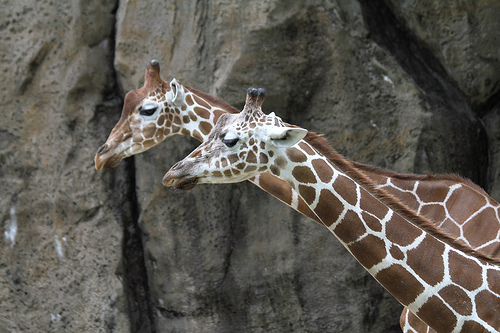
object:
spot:
[385, 213, 422, 247]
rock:
[113, 0, 486, 331]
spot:
[437, 283, 472, 315]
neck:
[270, 136, 500, 333]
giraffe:
[162, 87, 496, 333]